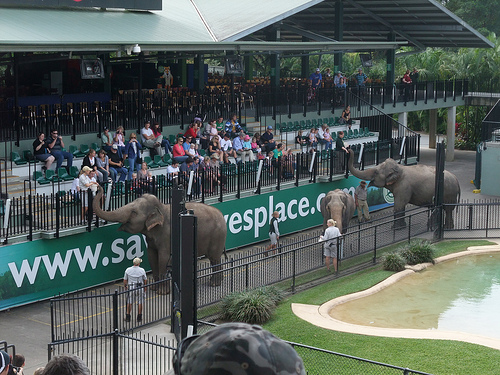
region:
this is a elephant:
[378, 155, 472, 220]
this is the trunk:
[340, 149, 368, 171]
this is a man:
[116, 252, 156, 298]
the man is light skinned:
[121, 277, 128, 287]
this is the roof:
[44, 29, 133, 51]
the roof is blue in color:
[73, 16, 123, 38]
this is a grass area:
[320, 332, 367, 372]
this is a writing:
[0, 245, 90, 284]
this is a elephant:
[362, 135, 466, 207]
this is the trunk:
[91, 192, 113, 217]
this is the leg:
[386, 195, 411, 219]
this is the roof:
[82, 17, 125, 32]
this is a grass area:
[341, 332, 389, 352]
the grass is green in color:
[313, 323, 338, 359]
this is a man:
[123, 250, 157, 342]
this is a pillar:
[436, 107, 456, 156]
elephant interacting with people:
[58, 160, 245, 276]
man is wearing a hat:
[115, 249, 152, 272]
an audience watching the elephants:
[2, 114, 303, 182]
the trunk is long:
[73, 177, 129, 229]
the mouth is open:
[101, 213, 141, 236]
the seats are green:
[275, 107, 377, 149]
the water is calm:
[341, 235, 498, 325]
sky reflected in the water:
[432, 274, 497, 335]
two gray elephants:
[84, 141, 485, 299]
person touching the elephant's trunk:
[81, 162, 115, 231]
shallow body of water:
[317, 243, 498, 355]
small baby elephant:
[313, 185, 359, 244]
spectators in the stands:
[17, 96, 360, 211]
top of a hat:
[158, 316, 315, 373]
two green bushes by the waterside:
[373, 238, 443, 271]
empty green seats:
[31, 158, 83, 186]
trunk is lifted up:
[344, 142, 374, 182]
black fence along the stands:
[0, 133, 422, 245]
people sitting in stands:
[28, 123, 273, 205]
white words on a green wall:
[5, 178, 384, 305]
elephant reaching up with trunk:
[343, 143, 460, 230]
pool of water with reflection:
[325, 249, 496, 349]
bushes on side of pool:
[378, 239, 435, 274]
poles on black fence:
[46, 330, 165, 373]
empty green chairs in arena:
[275, 115, 339, 136]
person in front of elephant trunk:
[77, 167, 97, 220]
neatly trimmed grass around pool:
[261, 237, 486, 371]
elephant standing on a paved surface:
[94, 191, 230, 296]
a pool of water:
[311, 221, 499, 352]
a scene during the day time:
[11, 9, 483, 368]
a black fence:
[18, 132, 428, 243]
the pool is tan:
[292, 308, 357, 355]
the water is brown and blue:
[357, 287, 466, 325]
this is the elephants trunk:
[77, 191, 122, 233]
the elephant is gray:
[116, 212, 226, 286]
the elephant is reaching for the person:
[284, 150, 371, 186]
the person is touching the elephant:
[325, 133, 355, 165]